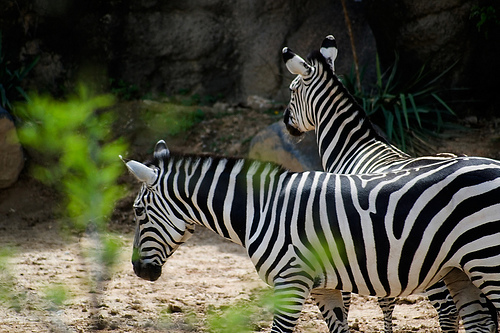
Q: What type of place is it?
A: It is a park.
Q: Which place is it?
A: It is a park.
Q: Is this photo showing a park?
A: Yes, it is showing a park.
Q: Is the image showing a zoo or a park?
A: It is showing a park.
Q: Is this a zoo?
A: No, it is a park.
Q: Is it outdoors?
A: Yes, it is outdoors.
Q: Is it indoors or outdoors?
A: It is outdoors.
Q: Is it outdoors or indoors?
A: It is outdoors.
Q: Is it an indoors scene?
A: No, it is outdoors.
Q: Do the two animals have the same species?
A: Yes, all the animals are zebras.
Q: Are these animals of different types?
A: No, all the animals are zebras.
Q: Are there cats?
A: No, there are no cats.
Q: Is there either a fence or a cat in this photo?
A: No, there are no cats or fences.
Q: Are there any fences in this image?
A: No, there are no fences.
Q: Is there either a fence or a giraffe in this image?
A: No, there are no fences or giraffes.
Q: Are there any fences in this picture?
A: No, there are no fences.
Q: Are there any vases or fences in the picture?
A: No, there are no fences or vases.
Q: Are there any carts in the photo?
A: No, there are no carts.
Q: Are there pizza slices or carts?
A: No, there are no carts or pizza slices.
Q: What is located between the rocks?
A: The plant is between the rocks.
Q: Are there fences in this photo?
A: No, there are no fences.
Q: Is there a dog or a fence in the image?
A: No, there are no fences or dogs.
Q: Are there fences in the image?
A: No, there are no fences.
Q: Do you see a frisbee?
A: No, there are no frisbees.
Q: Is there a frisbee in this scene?
A: No, there are no frisbees.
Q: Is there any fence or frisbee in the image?
A: No, there are no frisbees or fences.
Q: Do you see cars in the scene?
A: No, there are no cars.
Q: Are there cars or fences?
A: No, there are no cars or fences.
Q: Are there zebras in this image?
A: Yes, there is a zebra.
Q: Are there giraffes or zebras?
A: Yes, there is a zebra.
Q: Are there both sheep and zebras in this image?
A: No, there is a zebra but no sheep.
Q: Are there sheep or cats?
A: No, there are no cats or sheep.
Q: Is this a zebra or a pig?
A: This is a zebra.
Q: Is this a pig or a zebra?
A: This is a zebra.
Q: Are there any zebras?
A: Yes, there is a zebra.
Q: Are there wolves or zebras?
A: Yes, there is a zebra.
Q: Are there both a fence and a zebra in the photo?
A: No, there is a zebra but no fences.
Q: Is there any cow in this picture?
A: No, there are no cows.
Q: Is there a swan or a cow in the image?
A: No, there are no cows or swans.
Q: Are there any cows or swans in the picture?
A: No, there are no cows or swans.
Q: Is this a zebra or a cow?
A: This is a zebra.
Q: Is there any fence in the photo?
A: No, there are no fences.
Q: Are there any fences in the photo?
A: No, there are no fences.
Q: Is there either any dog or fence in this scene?
A: No, there are no fences or dogs.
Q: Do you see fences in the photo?
A: No, there are no fences.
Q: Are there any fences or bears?
A: No, there are no fences or bears.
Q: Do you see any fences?
A: No, there are no fences.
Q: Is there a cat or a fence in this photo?
A: No, there are no fences or cats.